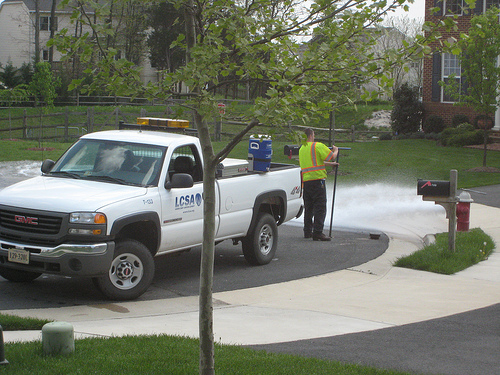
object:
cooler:
[246, 135, 274, 176]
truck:
[189, 117, 258, 375]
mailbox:
[416, 178, 448, 197]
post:
[417, 169, 457, 253]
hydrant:
[454, 190, 473, 232]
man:
[298, 127, 339, 242]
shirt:
[297, 141, 333, 182]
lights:
[136, 116, 191, 132]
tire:
[92, 242, 156, 300]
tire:
[242, 211, 278, 267]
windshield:
[40, 138, 170, 190]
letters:
[13, 213, 39, 227]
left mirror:
[164, 171, 195, 190]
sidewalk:
[0, 182, 499, 347]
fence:
[0, 111, 396, 141]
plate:
[7, 249, 32, 265]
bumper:
[0, 240, 117, 279]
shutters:
[431, 0, 486, 106]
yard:
[0, 103, 499, 375]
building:
[0, 0, 206, 99]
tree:
[42, 0, 499, 375]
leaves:
[450, 47, 462, 58]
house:
[420, 0, 500, 130]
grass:
[392, 227, 497, 275]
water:
[294, 182, 444, 227]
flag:
[420, 180, 434, 190]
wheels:
[93, 210, 279, 305]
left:
[3, 0, 276, 374]